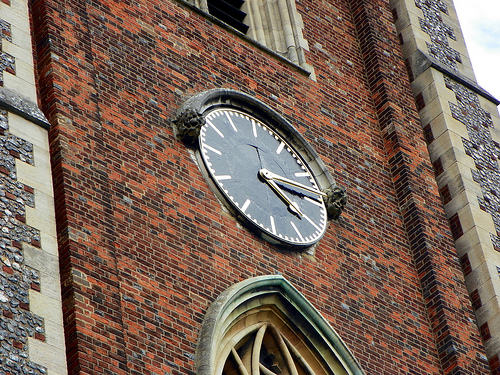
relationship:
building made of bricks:
[6, 4, 495, 370] [5, 5, 497, 373]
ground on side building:
[422, 149, 460, 186] [6, 4, 495, 370]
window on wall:
[226, 260, 329, 363] [86, 0, 445, 373]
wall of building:
[86, 0, 445, 373] [6, 4, 495, 370]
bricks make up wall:
[54, 8, 477, 371] [4, 12, 494, 372]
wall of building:
[4, 12, 494, 372] [6, 4, 495, 370]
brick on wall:
[312, 86, 389, 146] [0, 20, 63, 370]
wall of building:
[65, 15, 175, 114] [6, 4, 495, 370]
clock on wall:
[170, 62, 328, 252] [86, 0, 445, 373]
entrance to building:
[196, 282, 339, 371] [40, 16, 400, 369]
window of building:
[176, 0, 321, 77] [6, 4, 495, 370]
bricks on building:
[135, 201, 210, 263] [6, 4, 495, 370]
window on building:
[176, 0, 321, 77] [6, 4, 495, 370]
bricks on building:
[2, 265, 15, 274] [6, 4, 495, 370]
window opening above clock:
[176, 0, 321, 77] [197, 104, 329, 248]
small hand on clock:
[266, 180, 305, 220] [197, 104, 329, 248]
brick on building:
[437, 143, 477, 170] [6, 4, 495, 370]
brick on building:
[423, 134, 467, 161] [6, 4, 495, 370]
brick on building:
[425, 111, 473, 139] [6, 4, 495, 370]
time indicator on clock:
[222, 109, 242, 133] [183, 74, 365, 264]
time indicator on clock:
[275, 139, 287, 153] [178, 84, 377, 253]